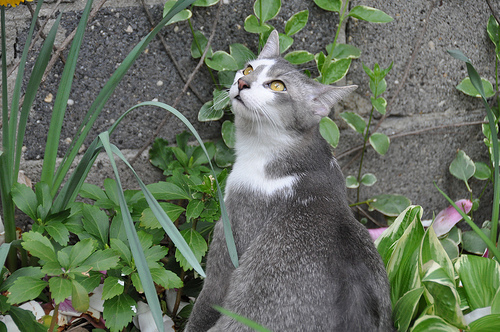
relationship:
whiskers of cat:
[259, 104, 289, 131] [182, 36, 418, 330]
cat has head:
[195, 25, 397, 330] [221, 26, 360, 151]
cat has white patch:
[182, 36, 418, 330] [236, 122, 261, 177]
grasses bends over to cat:
[0, 1, 238, 332] [146, 45, 406, 329]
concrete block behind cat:
[376, 36, 451, 206] [146, 45, 406, 329]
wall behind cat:
[370, 5, 456, 182] [195, 25, 397, 330]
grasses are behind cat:
[4, 1, 239, 329] [141, 36, 440, 328]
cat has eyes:
[201, 41, 368, 314] [261, 77, 302, 89]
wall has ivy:
[4, 4, 499, 246] [171, 0, 262, 158]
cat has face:
[195, 25, 397, 330] [224, 32, 361, 124]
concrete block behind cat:
[376, 36, 468, 189] [154, 23, 398, 330]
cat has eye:
[195, 25, 397, 330] [266, 75, 287, 95]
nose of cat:
[236, 76, 251, 91] [195, 25, 397, 330]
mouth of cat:
[229, 90, 254, 111] [179, 28, 393, 330]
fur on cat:
[220, 83, 295, 199] [195, 25, 397, 330]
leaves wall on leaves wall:
[432, 46, 494, 163] [6, 109, 186, 321]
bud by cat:
[432, 197, 477, 237] [162, 28, 381, 330]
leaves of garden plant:
[447, 143, 489, 190] [375, 204, 495, 316]